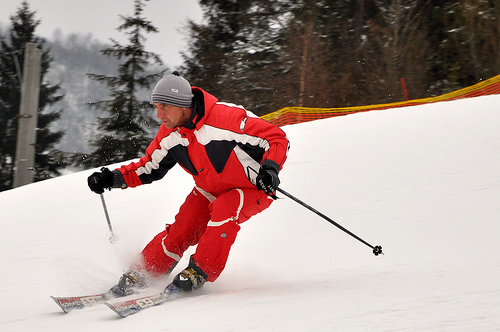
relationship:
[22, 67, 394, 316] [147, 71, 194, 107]
man wearing hat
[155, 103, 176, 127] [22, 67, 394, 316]
face of man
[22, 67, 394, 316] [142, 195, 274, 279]
man wearing pants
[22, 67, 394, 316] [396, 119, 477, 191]
man skiing in snow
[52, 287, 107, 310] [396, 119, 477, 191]
ski on top of snow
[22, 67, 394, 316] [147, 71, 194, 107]
man wearing a hat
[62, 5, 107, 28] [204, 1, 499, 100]
sky above trees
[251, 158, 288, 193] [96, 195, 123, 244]
glove holding ski pole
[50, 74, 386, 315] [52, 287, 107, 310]
man on ski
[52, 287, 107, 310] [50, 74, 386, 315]
ski on man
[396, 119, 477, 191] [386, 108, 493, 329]
snow on ground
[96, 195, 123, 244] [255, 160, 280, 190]
ski pole in hand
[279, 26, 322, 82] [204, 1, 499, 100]
branch on trees